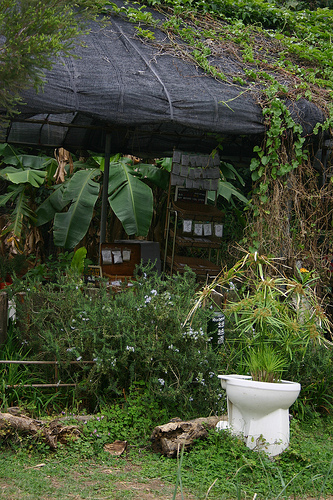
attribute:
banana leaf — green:
[107, 162, 154, 239]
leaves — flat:
[47, 151, 152, 283]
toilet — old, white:
[215, 365, 305, 461]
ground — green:
[0, 408, 327, 499]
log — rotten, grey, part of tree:
[2, 408, 87, 455]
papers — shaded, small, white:
[183, 218, 223, 239]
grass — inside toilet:
[242, 344, 293, 382]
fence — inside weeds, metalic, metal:
[3, 359, 138, 385]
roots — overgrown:
[234, 170, 332, 310]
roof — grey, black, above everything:
[20, 11, 325, 137]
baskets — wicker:
[169, 200, 229, 251]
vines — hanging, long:
[250, 121, 281, 224]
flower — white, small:
[134, 289, 164, 311]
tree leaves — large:
[0, 150, 168, 251]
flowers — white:
[133, 282, 175, 313]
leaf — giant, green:
[107, 162, 154, 239]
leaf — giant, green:
[55, 165, 100, 250]